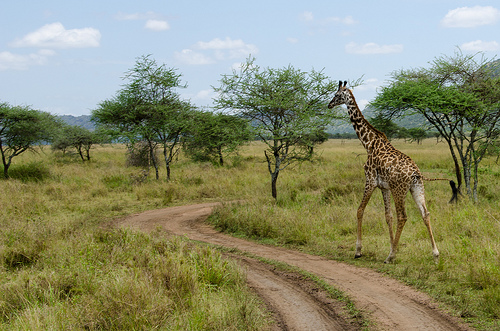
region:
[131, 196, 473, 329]
Dirt road through field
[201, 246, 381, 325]
Grass covered median in road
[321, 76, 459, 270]
Griaffe crossing dirt road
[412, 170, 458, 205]
Extended tail of giraffe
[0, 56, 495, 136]
Mountains in background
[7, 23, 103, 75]
Clouds in blue sky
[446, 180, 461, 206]
Black hairs on giraffe tail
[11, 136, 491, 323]
Green grass covered plains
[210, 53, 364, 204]
Small tree near road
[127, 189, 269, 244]
Right turn in dirt road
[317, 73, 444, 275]
giraffe in the grass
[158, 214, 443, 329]
road in the grass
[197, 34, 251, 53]
white cloud in the sky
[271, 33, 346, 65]
blue sky in the distance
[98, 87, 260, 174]
green trees in the grass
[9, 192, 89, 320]
green grass on the ground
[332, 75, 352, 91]
horns of a giraffe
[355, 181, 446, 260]
legs of a giraffe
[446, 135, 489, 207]
trunk of a tree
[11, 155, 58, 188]
shadow on the ground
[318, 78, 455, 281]
the giraffe is in the wild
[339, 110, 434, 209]
the spots are brown and white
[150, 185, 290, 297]
the road is curved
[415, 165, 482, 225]
tail is up in the air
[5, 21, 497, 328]
the scene is outdoors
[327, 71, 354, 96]
the horns are two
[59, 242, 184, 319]
the grass is brown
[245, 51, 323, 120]
the trees have thorns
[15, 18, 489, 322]
the season is summer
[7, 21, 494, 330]
the scene is in the grasslands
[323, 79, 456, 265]
giraffe running in a field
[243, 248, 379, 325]
grass growing in the middle of a road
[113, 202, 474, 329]
dirt road winding through a field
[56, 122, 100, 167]
two trees with green leaves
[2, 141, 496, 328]
grassy field with weeds growing in it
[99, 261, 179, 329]
a weed growing in a field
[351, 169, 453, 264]
a giraffe's long, spindly legs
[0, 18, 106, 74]
White fluffy clouds high in the sky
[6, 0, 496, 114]
blue sky filled with white clouds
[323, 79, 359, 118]
head of a giraffe running in a field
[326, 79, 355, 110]
Brown and white head of a giraffe.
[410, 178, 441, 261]
Extended furthest back leg of a giraffe.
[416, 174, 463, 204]
Tail of a giraffe that is brown, white and black in color.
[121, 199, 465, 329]
Brown dirt road.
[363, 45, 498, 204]
A brown and green tree to the right of a giraffe.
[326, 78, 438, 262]
A brown and white giraffe.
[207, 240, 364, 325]
Line of grass in the middle of the dirt road.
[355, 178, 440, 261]
White and brown spotted four legs of a giraffe.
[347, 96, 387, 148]
Brown and white spotted neck of a giraffe between a head and body.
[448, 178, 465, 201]
Black hair on the end of a giraffes tail.